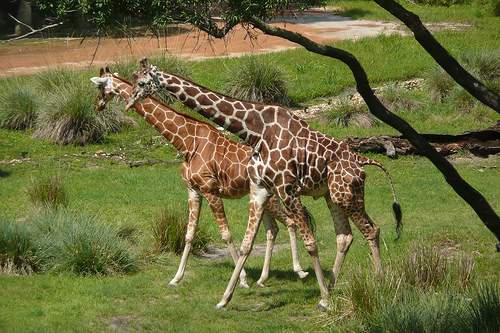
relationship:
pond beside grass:
[1, 21, 360, 71] [3, 65, 498, 332]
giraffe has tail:
[127, 59, 406, 311] [357, 154, 419, 247]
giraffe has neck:
[127, 59, 406, 311] [125, 53, 268, 155]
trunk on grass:
[308, 119, 499, 161] [3, 65, 498, 332]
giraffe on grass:
[127, 59, 406, 311] [3, 65, 498, 332]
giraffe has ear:
[82, 54, 313, 294] [83, 69, 114, 90]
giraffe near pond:
[127, 59, 406, 311] [1, 21, 360, 71]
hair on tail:
[390, 197, 408, 243] [357, 154, 419, 247]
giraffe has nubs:
[127, 59, 406, 311] [130, 53, 160, 82]